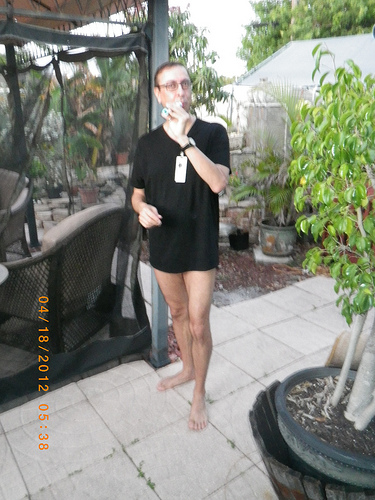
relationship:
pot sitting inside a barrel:
[274, 367, 374, 487] [245, 330, 373, 499]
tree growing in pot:
[293, 35, 372, 420] [245, 359, 353, 477]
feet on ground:
[151, 362, 214, 434] [0, 210, 371, 498]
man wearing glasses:
[129, 62, 233, 430] [150, 76, 195, 91]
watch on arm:
[181, 136, 196, 152] [165, 99, 237, 189]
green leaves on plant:
[297, 102, 339, 195] [281, 72, 374, 434]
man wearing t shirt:
[129, 61, 231, 432] [129, 113, 231, 269]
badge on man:
[174, 151, 188, 184] [117, 60, 242, 431]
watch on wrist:
[180, 132, 195, 156] [176, 130, 198, 154]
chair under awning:
[0, 203, 123, 361] [10, 2, 136, 58]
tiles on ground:
[0, 268, 367, 498] [339, 83, 364, 100]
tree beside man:
[286, 39, 375, 432] [129, 62, 233, 430]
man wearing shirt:
[129, 61, 231, 432] [136, 117, 237, 234]